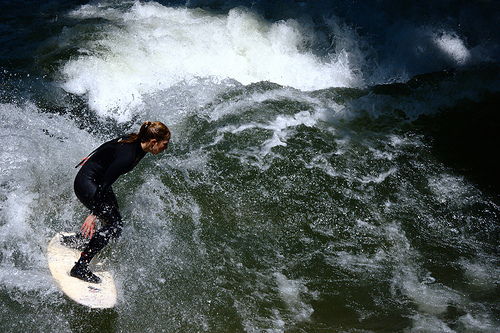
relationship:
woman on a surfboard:
[64, 120, 171, 283] [46, 231, 117, 310]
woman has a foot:
[64, 120, 171, 283] [72, 255, 104, 284]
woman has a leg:
[64, 120, 171, 283] [72, 206, 123, 284]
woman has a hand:
[64, 120, 171, 283] [80, 214, 97, 240]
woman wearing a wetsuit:
[64, 120, 171, 283] [72, 136, 149, 284]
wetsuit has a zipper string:
[72, 136, 149, 284] [73, 134, 123, 168]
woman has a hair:
[64, 120, 171, 283] [120, 121, 171, 153]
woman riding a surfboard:
[64, 120, 171, 283] [46, 231, 117, 310]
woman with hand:
[64, 120, 171, 283] [80, 214, 97, 240]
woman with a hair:
[64, 120, 171, 283] [120, 121, 171, 153]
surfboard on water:
[46, 231, 117, 310] [3, 4, 497, 332]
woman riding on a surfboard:
[64, 120, 171, 283] [46, 231, 117, 310]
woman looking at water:
[64, 120, 171, 283] [3, 4, 497, 332]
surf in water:
[60, 3, 356, 122] [3, 4, 497, 332]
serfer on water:
[64, 120, 171, 283] [3, 4, 497, 332]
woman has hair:
[64, 120, 171, 283] [123, 121, 173, 143]